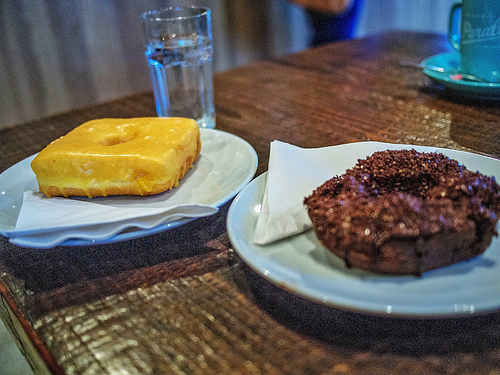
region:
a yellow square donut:
[11, 82, 226, 222]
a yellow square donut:
[27, 90, 136, 172]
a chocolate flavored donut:
[288, 142, 496, 308]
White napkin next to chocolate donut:
[255, 131, 385, 241]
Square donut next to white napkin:
[30, 115, 195, 190]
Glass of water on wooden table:
[140, 5, 215, 125]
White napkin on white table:
[0, 185, 210, 240]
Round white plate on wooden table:
[225, 140, 495, 320]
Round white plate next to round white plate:
[0, 120, 250, 240]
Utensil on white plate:
[395, 55, 480, 80]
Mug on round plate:
[440, 0, 495, 80]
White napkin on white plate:
[250, 135, 390, 240]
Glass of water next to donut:
[142, 8, 217, 128]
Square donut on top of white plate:
[30, 117, 201, 189]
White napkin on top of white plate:
[5, 190, 215, 250]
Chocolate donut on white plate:
[300, 145, 495, 275]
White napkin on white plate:
[246, 135, 371, 241]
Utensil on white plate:
[395, 55, 485, 81]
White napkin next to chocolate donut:
[247, 133, 373, 250]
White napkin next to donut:
[2, 188, 221, 248]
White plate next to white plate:
[0, 122, 257, 244]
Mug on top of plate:
[442, 0, 497, 79]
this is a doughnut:
[27, 97, 207, 209]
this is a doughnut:
[293, 151, 491, 274]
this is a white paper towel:
[238, 143, 354, 243]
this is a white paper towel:
[10, 178, 222, 270]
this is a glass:
[143, 6, 240, 138]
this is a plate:
[224, 109, 497, 353]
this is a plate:
[3, 106, 268, 263]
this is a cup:
[444, 3, 495, 78]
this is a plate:
[423, 31, 494, 111]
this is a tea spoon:
[404, 43, 486, 87]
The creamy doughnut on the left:
[27, 114, 200, 194]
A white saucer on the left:
[0, 117, 258, 244]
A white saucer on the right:
[227, 142, 498, 319]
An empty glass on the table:
[142, 7, 217, 131]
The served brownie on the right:
[304, 137, 499, 275]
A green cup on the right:
[402, 0, 499, 99]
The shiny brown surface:
[0, 29, 498, 374]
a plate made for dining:
[227, 137, 499, 317]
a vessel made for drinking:
[137, 7, 220, 130]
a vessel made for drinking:
[441, 0, 498, 75]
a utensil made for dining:
[398, 52, 489, 89]